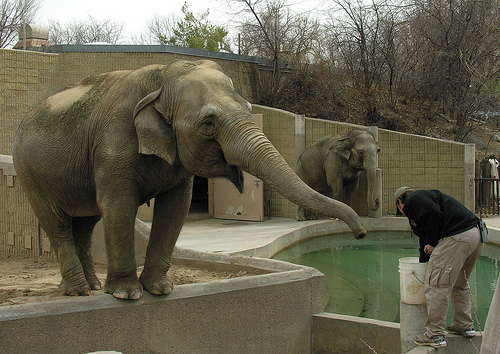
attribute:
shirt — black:
[400, 188, 482, 263]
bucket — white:
[396, 254, 428, 305]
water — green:
[269, 228, 485, 332]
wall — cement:
[250, 101, 476, 218]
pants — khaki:
[420, 226, 484, 337]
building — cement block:
[0, 20, 476, 220]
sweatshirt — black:
[400, 185, 483, 264]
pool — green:
[287, 253, 436, 351]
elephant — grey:
[304, 143, 405, 227]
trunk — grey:
[250, 116, 387, 253]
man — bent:
[414, 169, 492, 314]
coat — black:
[396, 173, 485, 253]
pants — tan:
[410, 211, 490, 344]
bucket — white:
[385, 213, 412, 308]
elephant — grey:
[75, 173, 219, 295]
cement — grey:
[298, 283, 412, 345]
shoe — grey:
[405, 316, 453, 348]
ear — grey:
[103, 102, 201, 167]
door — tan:
[217, 108, 310, 267]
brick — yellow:
[428, 137, 470, 151]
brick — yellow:
[428, 133, 458, 165]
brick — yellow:
[411, 131, 457, 170]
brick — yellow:
[383, 112, 406, 163]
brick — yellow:
[392, 149, 417, 185]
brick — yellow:
[279, 105, 315, 129]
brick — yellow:
[382, 170, 403, 195]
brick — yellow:
[300, 91, 340, 130]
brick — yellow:
[322, 126, 364, 133]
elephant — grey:
[27, 58, 279, 238]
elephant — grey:
[279, 89, 454, 279]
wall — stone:
[264, 103, 489, 226]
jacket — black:
[401, 189, 481, 258]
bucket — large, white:
[393, 257, 435, 322]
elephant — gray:
[15, 54, 427, 330]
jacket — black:
[393, 180, 473, 250]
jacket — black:
[403, 193, 479, 251]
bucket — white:
[395, 256, 423, 302]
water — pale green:
[305, 242, 395, 308]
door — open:
[166, 165, 274, 215]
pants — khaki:
[405, 210, 492, 348]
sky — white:
[28, 0, 336, 43]